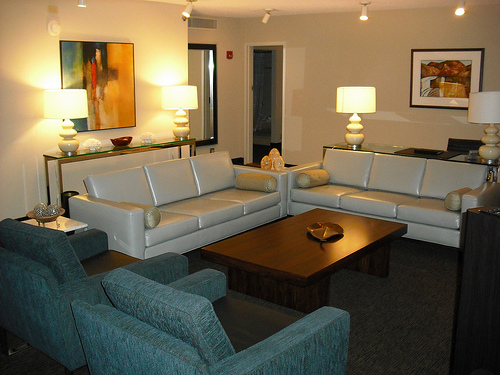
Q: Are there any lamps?
A: Yes, there is a lamp.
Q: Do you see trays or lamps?
A: Yes, there is a lamp.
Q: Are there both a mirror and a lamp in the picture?
A: Yes, there are both a lamp and a mirror.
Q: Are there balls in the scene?
A: No, there are no balls.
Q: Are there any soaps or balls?
A: No, there are no balls or soaps.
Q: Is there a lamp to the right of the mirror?
A: Yes, there is a lamp to the right of the mirror.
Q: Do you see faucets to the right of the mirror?
A: No, there is a lamp to the right of the mirror.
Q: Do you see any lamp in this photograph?
A: Yes, there is a lamp.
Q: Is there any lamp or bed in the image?
A: Yes, there is a lamp.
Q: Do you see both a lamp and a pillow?
A: Yes, there are both a lamp and a pillow.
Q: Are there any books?
A: No, there are no books.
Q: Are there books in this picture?
A: No, there are no books.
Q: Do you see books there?
A: No, there are no books.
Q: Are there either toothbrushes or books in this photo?
A: No, there are no books or toothbrushes.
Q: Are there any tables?
A: Yes, there is a table.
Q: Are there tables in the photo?
A: Yes, there is a table.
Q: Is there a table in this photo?
A: Yes, there is a table.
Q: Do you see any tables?
A: Yes, there is a table.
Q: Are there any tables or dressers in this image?
A: Yes, there is a table.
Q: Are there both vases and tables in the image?
A: No, there is a table but no vases.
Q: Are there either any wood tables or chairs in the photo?
A: Yes, there is a wood table.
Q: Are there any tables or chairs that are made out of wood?
A: Yes, the table is made of wood.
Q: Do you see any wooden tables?
A: Yes, there is a wood table.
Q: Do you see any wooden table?
A: Yes, there is a wood table.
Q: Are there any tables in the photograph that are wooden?
A: Yes, there is a table that is wooden.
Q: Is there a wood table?
A: Yes, there is a table that is made of wood.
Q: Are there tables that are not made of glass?
A: Yes, there is a table that is made of wood.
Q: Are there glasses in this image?
A: No, there are no glasses.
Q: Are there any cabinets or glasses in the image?
A: No, there are no glasses or cabinets.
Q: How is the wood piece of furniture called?
A: The piece of furniture is a table.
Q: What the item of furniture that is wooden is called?
A: The piece of furniture is a table.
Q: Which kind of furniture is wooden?
A: The furniture is a table.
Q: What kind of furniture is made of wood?
A: The furniture is a table.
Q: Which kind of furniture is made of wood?
A: The furniture is a table.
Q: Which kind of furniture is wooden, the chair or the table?
A: The table is wooden.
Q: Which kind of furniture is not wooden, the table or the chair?
A: The chair is not wooden.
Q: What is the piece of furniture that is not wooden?
A: The piece of furniture is a chair.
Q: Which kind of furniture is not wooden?
A: The furniture is a chair.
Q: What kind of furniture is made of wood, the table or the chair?
A: The table is made of wood.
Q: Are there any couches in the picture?
A: Yes, there is a couch.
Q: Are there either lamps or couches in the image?
A: Yes, there is a couch.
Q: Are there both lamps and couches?
A: Yes, there are both a couch and a lamp.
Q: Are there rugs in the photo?
A: No, there are no rugs.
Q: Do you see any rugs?
A: No, there are no rugs.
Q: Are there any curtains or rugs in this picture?
A: No, there are no rugs or curtains.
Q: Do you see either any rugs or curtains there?
A: No, there are no rugs or curtains.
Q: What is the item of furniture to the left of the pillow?
A: The piece of furniture is a couch.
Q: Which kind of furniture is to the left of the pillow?
A: The piece of furniture is a couch.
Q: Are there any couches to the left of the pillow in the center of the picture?
A: Yes, there is a couch to the left of the pillow.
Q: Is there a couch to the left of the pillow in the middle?
A: Yes, there is a couch to the left of the pillow.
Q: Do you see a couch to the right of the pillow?
A: No, the couch is to the left of the pillow.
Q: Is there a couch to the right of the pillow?
A: No, the couch is to the left of the pillow.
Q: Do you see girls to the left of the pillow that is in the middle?
A: No, there is a couch to the left of the pillow.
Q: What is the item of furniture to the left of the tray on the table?
A: The piece of furniture is a couch.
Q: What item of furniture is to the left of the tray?
A: The piece of furniture is a couch.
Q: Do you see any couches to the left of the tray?
A: Yes, there is a couch to the left of the tray.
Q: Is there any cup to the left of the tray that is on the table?
A: No, there is a couch to the left of the tray.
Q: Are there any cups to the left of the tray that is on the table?
A: No, there is a couch to the left of the tray.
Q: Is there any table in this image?
A: Yes, there is a table.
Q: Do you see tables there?
A: Yes, there is a table.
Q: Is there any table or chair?
A: Yes, there is a table.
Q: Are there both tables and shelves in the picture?
A: No, there is a table but no shelves.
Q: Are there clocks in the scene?
A: No, there are no clocks.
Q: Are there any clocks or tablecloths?
A: No, there are no clocks or tablecloths.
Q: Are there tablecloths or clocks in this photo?
A: No, there are no clocks or tablecloths.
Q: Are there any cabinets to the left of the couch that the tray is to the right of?
A: No, there is a table to the left of the couch.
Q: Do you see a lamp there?
A: Yes, there is a lamp.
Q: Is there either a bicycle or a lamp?
A: Yes, there is a lamp.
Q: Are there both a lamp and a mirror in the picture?
A: Yes, there are both a lamp and a mirror.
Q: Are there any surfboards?
A: No, there are no surfboards.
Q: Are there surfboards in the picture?
A: No, there are no surfboards.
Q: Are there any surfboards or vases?
A: No, there are no surfboards or vases.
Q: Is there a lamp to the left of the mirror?
A: Yes, there is a lamp to the left of the mirror.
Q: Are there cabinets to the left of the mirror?
A: No, there is a lamp to the left of the mirror.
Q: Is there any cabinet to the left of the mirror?
A: No, there is a lamp to the left of the mirror.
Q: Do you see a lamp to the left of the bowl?
A: Yes, there is a lamp to the left of the bowl.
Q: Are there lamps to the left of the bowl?
A: Yes, there is a lamp to the left of the bowl.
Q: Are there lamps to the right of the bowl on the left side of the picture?
A: No, the lamp is to the left of the bowl.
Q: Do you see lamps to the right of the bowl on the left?
A: No, the lamp is to the left of the bowl.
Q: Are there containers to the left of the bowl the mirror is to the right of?
A: No, there is a lamp to the left of the bowl.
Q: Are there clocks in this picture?
A: No, there are no clocks.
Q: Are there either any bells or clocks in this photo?
A: No, there are no clocks or bells.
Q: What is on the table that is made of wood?
A: The tray is on the table.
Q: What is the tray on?
A: The tray is on the table.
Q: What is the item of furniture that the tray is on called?
A: The piece of furniture is a table.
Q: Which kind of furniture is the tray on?
A: The tray is on the table.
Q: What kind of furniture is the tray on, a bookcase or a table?
A: The tray is on a table.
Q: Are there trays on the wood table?
A: Yes, there is a tray on the table.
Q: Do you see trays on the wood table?
A: Yes, there is a tray on the table.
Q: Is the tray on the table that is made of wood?
A: Yes, the tray is on the table.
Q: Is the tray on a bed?
A: No, the tray is on the table.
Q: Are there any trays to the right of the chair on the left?
A: Yes, there is a tray to the right of the chair.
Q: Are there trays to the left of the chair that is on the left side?
A: No, the tray is to the right of the chair.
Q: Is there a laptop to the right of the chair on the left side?
A: No, there is a tray to the right of the chair.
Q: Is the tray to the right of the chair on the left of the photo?
A: Yes, the tray is to the right of the chair.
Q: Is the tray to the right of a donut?
A: No, the tray is to the right of the chair.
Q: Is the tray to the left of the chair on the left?
A: No, the tray is to the right of the chair.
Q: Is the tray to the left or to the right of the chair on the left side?
A: The tray is to the right of the chair.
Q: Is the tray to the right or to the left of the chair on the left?
A: The tray is to the right of the chair.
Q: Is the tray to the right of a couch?
A: Yes, the tray is to the right of a couch.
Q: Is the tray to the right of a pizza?
A: No, the tray is to the right of a couch.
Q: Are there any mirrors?
A: Yes, there is a mirror.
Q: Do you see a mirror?
A: Yes, there is a mirror.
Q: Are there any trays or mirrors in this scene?
A: Yes, there is a mirror.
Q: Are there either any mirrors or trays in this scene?
A: Yes, there is a mirror.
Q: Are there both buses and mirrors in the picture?
A: No, there is a mirror but no buses.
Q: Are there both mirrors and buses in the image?
A: No, there is a mirror but no buses.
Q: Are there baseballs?
A: No, there are no baseballs.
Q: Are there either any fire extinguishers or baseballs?
A: No, there are no baseballs or fire extinguishers.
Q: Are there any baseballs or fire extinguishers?
A: No, there are no baseballs or fire extinguishers.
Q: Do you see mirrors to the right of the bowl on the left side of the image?
A: Yes, there is a mirror to the right of the bowl.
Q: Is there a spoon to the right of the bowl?
A: No, there is a mirror to the right of the bowl.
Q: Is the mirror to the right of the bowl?
A: Yes, the mirror is to the right of the bowl.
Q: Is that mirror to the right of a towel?
A: No, the mirror is to the right of the bowl.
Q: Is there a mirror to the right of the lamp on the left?
A: Yes, there is a mirror to the right of the lamp.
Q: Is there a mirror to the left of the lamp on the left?
A: No, the mirror is to the right of the lamp.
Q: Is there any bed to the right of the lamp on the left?
A: No, there is a mirror to the right of the lamp.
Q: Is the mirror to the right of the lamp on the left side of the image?
A: Yes, the mirror is to the right of the lamp.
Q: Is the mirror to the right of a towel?
A: No, the mirror is to the right of the lamp.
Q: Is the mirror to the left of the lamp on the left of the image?
A: No, the mirror is to the right of the lamp.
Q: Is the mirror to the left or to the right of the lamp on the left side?
A: The mirror is to the right of the lamp.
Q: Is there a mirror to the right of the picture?
A: Yes, there is a mirror to the right of the picture.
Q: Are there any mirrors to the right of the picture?
A: Yes, there is a mirror to the right of the picture.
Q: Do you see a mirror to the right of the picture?
A: Yes, there is a mirror to the right of the picture.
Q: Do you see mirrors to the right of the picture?
A: Yes, there is a mirror to the right of the picture.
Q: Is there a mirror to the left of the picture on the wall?
A: No, the mirror is to the right of the picture.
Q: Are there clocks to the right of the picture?
A: No, there is a mirror to the right of the picture.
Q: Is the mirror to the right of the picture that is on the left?
A: Yes, the mirror is to the right of the picture.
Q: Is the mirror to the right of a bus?
A: No, the mirror is to the right of the picture.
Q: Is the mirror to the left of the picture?
A: No, the mirror is to the right of the picture.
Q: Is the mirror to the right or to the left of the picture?
A: The mirror is to the right of the picture.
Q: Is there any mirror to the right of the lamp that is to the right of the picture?
A: Yes, there is a mirror to the right of the lamp.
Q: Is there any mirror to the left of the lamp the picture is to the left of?
A: No, the mirror is to the right of the lamp.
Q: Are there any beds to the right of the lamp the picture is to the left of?
A: No, there is a mirror to the right of the lamp.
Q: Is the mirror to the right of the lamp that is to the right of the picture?
A: Yes, the mirror is to the right of the lamp.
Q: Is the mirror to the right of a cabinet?
A: No, the mirror is to the right of the lamp.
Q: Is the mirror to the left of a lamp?
A: No, the mirror is to the right of a lamp.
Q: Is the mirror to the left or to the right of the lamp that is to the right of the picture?
A: The mirror is to the right of the lamp.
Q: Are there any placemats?
A: No, there are no placemats.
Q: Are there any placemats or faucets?
A: No, there are no placemats or faucets.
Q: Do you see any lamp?
A: Yes, there is a lamp.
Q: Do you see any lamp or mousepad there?
A: Yes, there is a lamp.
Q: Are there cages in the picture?
A: No, there are no cages.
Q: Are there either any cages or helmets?
A: No, there are no cages or helmets.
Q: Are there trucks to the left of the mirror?
A: No, there is a lamp to the left of the mirror.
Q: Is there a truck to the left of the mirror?
A: No, there is a lamp to the left of the mirror.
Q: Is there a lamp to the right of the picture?
A: Yes, there is a lamp to the right of the picture.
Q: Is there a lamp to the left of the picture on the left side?
A: No, the lamp is to the right of the picture.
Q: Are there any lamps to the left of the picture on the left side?
A: No, the lamp is to the right of the picture.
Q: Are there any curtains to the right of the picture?
A: No, there is a lamp to the right of the picture.